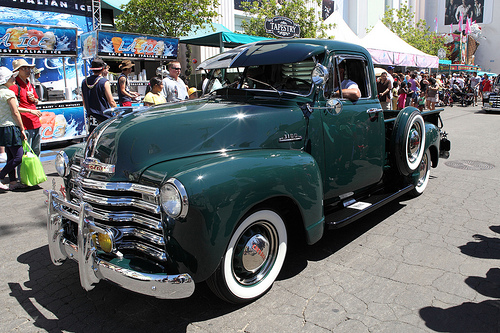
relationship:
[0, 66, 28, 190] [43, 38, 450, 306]
person near car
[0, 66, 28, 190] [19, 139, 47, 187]
person carrying bag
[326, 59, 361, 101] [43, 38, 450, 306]
man in car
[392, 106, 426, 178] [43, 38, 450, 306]
tire on side of car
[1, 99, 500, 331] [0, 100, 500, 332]
shadows on road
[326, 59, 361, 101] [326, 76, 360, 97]
man wearing a shirt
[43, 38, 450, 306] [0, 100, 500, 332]
car on road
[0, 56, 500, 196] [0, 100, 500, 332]
people on road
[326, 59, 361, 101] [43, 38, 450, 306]
man driving car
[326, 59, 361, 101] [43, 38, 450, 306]
man sitting in car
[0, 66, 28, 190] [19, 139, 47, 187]
person holding bag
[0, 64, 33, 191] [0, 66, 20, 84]
person wearing hat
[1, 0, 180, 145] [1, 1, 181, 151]
stall for ice cream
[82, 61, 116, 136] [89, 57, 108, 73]
man wearing cap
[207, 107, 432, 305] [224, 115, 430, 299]
tires have white walls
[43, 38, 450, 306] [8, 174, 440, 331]
car has a shadow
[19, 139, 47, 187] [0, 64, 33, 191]
bag carried by person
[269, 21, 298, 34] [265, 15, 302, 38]
tapestry on sign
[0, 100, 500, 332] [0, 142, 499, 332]
road has cracks